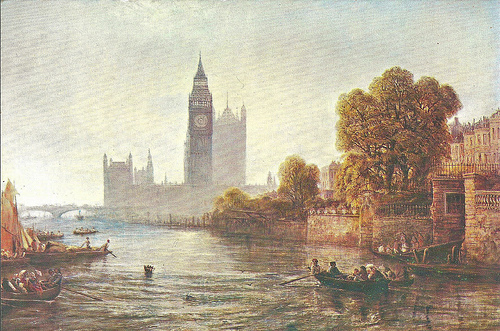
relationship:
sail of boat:
[0, 181, 39, 266] [0, 251, 32, 267]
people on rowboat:
[44, 237, 117, 247] [13, 248, 114, 261]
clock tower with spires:
[185, 50, 214, 188] [193, 50, 207, 80]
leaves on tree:
[395, 112, 420, 154] [320, 54, 473, 231]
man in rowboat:
[311, 257, 327, 276] [238, 239, 484, 316]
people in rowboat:
[324, 255, 344, 279] [238, 239, 484, 316]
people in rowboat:
[347, 263, 359, 282] [238, 239, 484, 316]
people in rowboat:
[352, 260, 367, 280] [238, 239, 484, 316]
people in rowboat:
[369, 264, 385, 282] [238, 239, 484, 316]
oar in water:
[57, 284, 102, 303] [0, 217, 498, 327]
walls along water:
[209, 170, 476, 268] [0, 217, 498, 327]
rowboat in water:
[312, 270, 396, 295] [0, 217, 498, 327]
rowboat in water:
[392, 272, 416, 287] [0, 217, 498, 327]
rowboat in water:
[0, 275, 65, 305] [0, 217, 498, 327]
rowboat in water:
[13, 243, 114, 263] [0, 217, 498, 327]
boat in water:
[71, 226, 100, 237] [0, 217, 498, 327]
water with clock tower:
[0, 217, 498, 327] [188, 57, 213, 213]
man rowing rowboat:
[311, 257, 321, 274] [307, 265, 393, 296]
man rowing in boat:
[311, 257, 327, 276] [296, 263, 395, 303]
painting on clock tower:
[2, 2, 496, 323] [184, 50, 215, 188]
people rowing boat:
[9, 256, 77, 283] [71, 226, 100, 237]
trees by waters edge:
[327, 61, 465, 216] [278, 192, 398, 232]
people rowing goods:
[327, 261, 345, 280] [2, 239, 71, 261]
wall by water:
[303, 205, 364, 249] [0, 217, 498, 327]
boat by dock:
[366, 227, 470, 281] [420, 220, 498, 257]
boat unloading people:
[366, 227, 470, 281] [372, 227, 437, 257]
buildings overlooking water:
[424, 111, 497, 182] [0, 217, 500, 331]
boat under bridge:
[30, 223, 111, 245] [14, 193, 104, 224]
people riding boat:
[327, 261, 345, 280] [285, 257, 375, 314]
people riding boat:
[353, 266, 368, 282] [306, 265, 391, 293]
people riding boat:
[327, 261, 345, 280] [303, 246, 390, 281]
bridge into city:
[16, 201, 111, 226] [104, 50, 284, 220]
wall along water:
[231, 174, 498, 260] [0, 217, 498, 327]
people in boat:
[327, 261, 345, 280] [294, 257, 430, 314]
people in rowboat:
[48, 267, 63, 287] [0, 282, 63, 303]